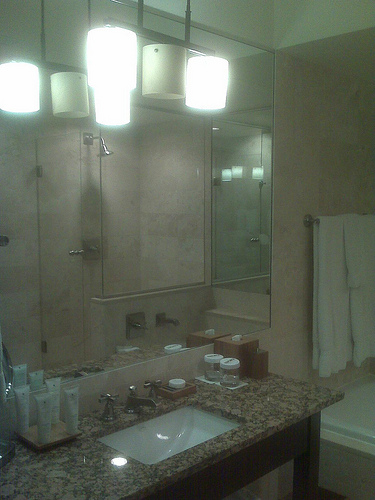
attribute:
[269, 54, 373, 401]
wall — white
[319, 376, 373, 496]
tub — white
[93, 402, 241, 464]
bowl — white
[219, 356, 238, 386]
jar — clear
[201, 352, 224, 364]
lid — white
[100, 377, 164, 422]
faucet — silver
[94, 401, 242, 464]
sink — shiny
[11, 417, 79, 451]
square — wood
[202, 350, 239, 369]
lids — white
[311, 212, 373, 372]
towels — white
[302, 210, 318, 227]
bar — silver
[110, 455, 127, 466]
spot — round, bright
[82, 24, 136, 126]
light — hanging, illuminated, longest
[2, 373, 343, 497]
counter — marble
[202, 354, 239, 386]
glasses — empty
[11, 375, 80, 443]
bottles — cleansers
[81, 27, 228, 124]
bathroom lights — on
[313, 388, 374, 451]
bathtub — white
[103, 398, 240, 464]
sink — white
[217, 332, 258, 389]
tissue box — wooden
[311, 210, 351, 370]
towel — white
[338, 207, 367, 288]
towel — white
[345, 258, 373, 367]
towel — white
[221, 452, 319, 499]
cabinet — wooden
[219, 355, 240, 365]
lid — white